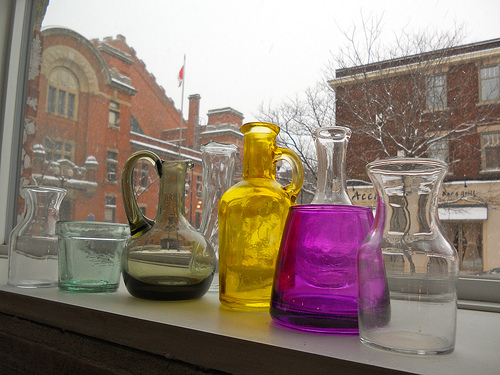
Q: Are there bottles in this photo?
A: Yes, there is a bottle.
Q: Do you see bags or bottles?
A: Yes, there is a bottle.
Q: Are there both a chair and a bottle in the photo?
A: No, there is a bottle but no chairs.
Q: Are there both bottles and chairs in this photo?
A: No, there is a bottle but no chairs.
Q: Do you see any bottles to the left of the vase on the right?
A: Yes, there is a bottle to the left of the vase.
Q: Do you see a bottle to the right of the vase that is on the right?
A: No, the bottle is to the left of the vase.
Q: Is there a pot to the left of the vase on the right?
A: No, there is a bottle to the left of the vase.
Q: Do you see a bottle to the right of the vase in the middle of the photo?
A: Yes, there is a bottle to the right of the vase.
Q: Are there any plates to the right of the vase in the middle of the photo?
A: No, there is a bottle to the right of the vase.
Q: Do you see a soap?
A: No, there are no soaps.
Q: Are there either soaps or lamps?
A: No, there are no soaps or lamps.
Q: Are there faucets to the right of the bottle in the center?
A: No, there is a vase to the right of the bottle.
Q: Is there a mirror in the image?
A: No, there are no mirrors.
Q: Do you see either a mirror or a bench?
A: No, there are no mirrors or benches.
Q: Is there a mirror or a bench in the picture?
A: No, there are no mirrors or benches.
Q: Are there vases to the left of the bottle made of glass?
A: Yes, there is a vase to the left of the bottle.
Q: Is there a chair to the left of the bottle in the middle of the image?
A: No, there is a vase to the left of the bottle.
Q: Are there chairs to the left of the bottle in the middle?
A: No, there is a vase to the left of the bottle.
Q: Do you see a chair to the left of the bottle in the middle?
A: No, there is a vase to the left of the bottle.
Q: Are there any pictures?
A: No, there are no pictures.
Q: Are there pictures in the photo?
A: No, there are no pictures.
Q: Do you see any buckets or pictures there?
A: No, there are no pictures or buckets.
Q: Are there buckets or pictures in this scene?
A: No, there are no pictures or buckets.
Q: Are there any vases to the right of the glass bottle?
A: Yes, there is a vase to the right of the bottle.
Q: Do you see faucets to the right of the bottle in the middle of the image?
A: No, there is a vase to the right of the bottle.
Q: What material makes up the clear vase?
A: The vase is made of glass.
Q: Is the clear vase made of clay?
A: No, the vase is made of glass.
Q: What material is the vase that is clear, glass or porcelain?
A: The vase is made of glass.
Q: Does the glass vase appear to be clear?
A: Yes, the vase is clear.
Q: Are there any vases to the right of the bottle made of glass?
A: Yes, there is a vase to the right of the bottle.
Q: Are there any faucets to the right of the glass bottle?
A: No, there is a vase to the right of the bottle.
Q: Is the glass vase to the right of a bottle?
A: Yes, the vase is to the right of a bottle.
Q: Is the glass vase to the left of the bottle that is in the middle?
A: No, the vase is to the right of the bottle.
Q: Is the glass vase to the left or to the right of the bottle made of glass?
A: The vase is to the right of the bottle.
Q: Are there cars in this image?
A: No, there are no cars.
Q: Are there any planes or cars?
A: No, there are no cars or planes.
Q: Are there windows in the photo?
A: Yes, there is a window.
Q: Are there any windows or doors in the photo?
A: Yes, there is a window.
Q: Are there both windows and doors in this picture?
A: No, there is a window but no doors.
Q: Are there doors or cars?
A: No, there are no cars or doors.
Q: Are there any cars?
A: No, there are no cars.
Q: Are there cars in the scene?
A: No, there are no cars.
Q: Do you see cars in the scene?
A: No, there are no cars.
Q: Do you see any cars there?
A: No, there are no cars.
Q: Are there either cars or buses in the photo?
A: No, there are no cars or buses.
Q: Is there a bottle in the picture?
A: Yes, there is a bottle.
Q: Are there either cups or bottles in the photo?
A: Yes, there is a bottle.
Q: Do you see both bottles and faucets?
A: No, there is a bottle but no faucets.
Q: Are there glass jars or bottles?
A: Yes, there is a glass bottle.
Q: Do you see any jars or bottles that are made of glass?
A: Yes, the bottle is made of glass.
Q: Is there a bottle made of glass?
A: Yes, there is a bottle that is made of glass.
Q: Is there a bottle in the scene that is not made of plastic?
A: Yes, there is a bottle that is made of glass.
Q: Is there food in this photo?
A: No, there is no food.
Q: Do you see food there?
A: No, there is no food.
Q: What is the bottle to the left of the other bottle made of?
A: The bottle is made of glass.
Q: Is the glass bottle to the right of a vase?
A: No, the bottle is to the left of a vase.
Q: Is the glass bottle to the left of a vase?
A: No, the bottle is to the right of a vase.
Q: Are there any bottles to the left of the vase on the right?
A: Yes, there is a bottle to the left of the vase.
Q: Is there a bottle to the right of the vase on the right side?
A: No, the bottle is to the left of the vase.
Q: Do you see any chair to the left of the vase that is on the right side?
A: No, there is a bottle to the left of the vase.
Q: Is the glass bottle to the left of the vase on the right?
A: Yes, the bottle is to the left of the vase.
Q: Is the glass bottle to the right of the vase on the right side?
A: No, the bottle is to the left of the vase.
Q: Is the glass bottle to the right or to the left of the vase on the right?
A: The bottle is to the left of the vase.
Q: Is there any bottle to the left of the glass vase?
A: Yes, there is a bottle to the left of the vase.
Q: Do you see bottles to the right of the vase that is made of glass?
A: No, the bottle is to the left of the vase.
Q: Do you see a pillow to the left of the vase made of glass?
A: No, there is a bottle to the left of the vase.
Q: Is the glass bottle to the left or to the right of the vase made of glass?
A: The bottle is to the left of the vase.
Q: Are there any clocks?
A: No, there are no clocks.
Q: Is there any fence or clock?
A: No, there are no clocks or fences.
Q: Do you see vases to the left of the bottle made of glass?
A: Yes, there is a vase to the left of the bottle.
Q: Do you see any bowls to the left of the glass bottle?
A: No, there is a vase to the left of the bottle.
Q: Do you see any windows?
A: Yes, there is a window.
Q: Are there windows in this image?
A: Yes, there is a window.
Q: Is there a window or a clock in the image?
A: Yes, there is a window.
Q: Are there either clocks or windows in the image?
A: Yes, there is a window.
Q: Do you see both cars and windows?
A: No, there is a window but no cars.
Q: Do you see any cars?
A: No, there are no cars.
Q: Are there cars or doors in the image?
A: No, there are no cars or doors.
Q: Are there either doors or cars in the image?
A: No, there are no cars or doors.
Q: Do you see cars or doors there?
A: No, there are no cars or doors.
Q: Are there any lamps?
A: No, there are no lamps.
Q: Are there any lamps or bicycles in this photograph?
A: No, there are no lamps or bicycles.